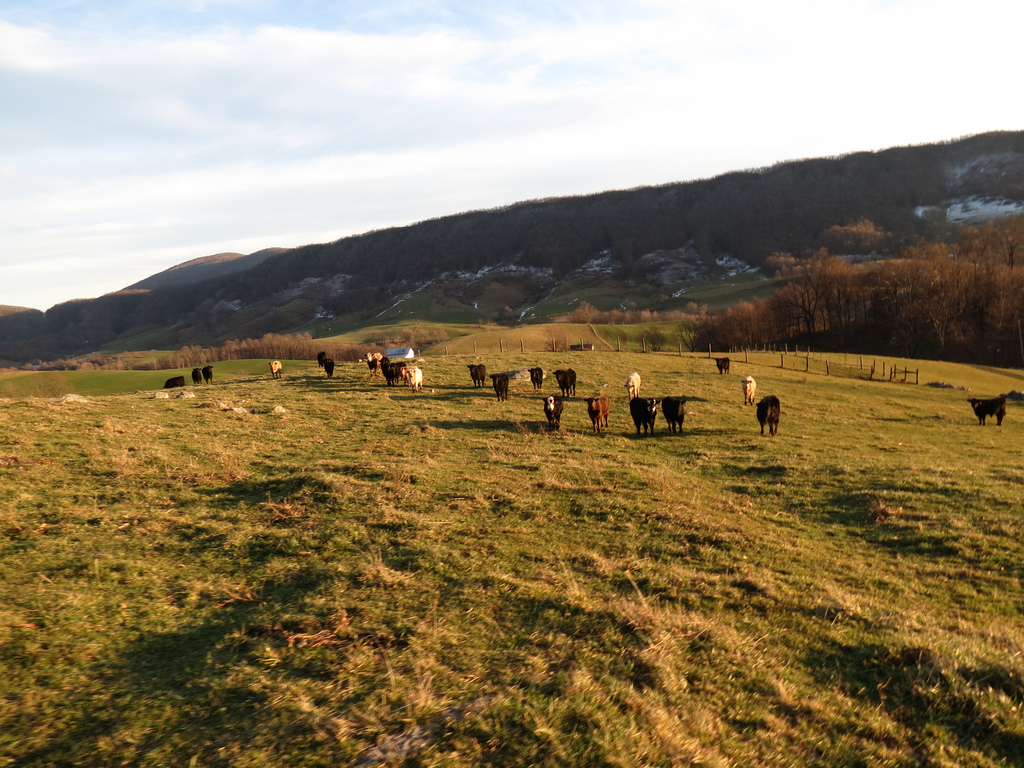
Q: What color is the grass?
A: Green.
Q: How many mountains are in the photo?
A: One.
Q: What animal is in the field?
A: Cows.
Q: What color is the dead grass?
A: Yellow.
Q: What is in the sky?
A: Clouds.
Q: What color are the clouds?
A: White.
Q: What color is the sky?
A: Blue.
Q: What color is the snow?
A: Bright white.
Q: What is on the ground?
A: Grass.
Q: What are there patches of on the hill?
A: Snow.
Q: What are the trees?
A: Bare.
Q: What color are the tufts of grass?
A: Brown.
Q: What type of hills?
A: Rolling.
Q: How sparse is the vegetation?
A: Dense.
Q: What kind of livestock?
A: Cattle.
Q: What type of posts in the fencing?
A: Wooden.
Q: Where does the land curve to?
A: Downward.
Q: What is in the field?
A: Cows.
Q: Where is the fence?
A: Pasture.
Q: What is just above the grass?
A: Snow.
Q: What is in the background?
A: Mountain.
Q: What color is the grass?
A: Brown and green.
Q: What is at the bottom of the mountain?
A: Trees.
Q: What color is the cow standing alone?
A: Black.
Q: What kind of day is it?
A: Sunny.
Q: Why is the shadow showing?
A: Hillside.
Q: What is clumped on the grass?
A: Hay.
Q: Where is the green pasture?
A: Hillside.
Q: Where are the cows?
A: In the field.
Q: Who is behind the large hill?
A: No one.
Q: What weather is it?
A: Sunny.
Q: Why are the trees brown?
A: The leaves are dead.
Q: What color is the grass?
A: Brown and green.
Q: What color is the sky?
A: Blue and white.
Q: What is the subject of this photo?
A: Cows.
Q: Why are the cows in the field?
A: To eat the grass.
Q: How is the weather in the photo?
A: Cloudy.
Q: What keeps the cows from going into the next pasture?
A: A fence.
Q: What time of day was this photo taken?
A: In the daytime.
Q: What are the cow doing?
A: Grazing in the field.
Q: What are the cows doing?
A: Eating.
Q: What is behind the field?
A: Large mountain.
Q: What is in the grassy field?
A: Animals.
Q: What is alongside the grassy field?
A: Fence.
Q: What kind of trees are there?
A: Tall.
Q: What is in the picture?
A: Herd of cattle.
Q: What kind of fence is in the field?
A: Wooden.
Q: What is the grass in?
A: A patch.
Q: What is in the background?
A: Mountains.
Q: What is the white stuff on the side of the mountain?
A: Snow.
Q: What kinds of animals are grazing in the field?
A: Cows.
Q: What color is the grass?
A: Green.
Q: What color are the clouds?
A: White.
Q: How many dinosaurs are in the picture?
A: Zero.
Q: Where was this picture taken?
A: In a field.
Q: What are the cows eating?
A: Grass.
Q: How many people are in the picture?
A: Zero.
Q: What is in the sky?
A: Clouds.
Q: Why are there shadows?
A: The sun is out.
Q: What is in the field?
A: Animals.